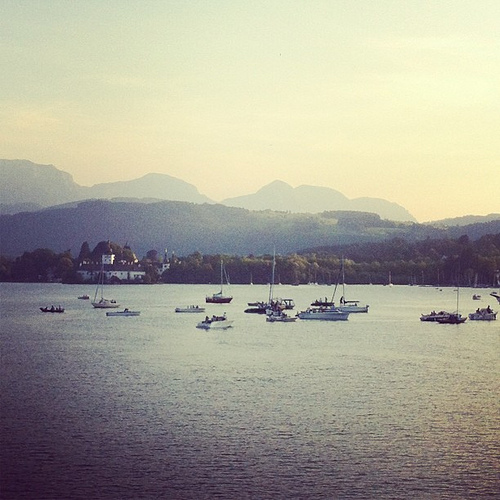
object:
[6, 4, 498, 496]
scene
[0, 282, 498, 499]
ocean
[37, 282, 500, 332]
boats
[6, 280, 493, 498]
water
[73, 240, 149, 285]
building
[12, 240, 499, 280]
background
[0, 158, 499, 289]
background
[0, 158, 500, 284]
hills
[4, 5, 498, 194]
sky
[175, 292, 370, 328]
boats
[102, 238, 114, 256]
steeple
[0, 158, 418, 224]
mountain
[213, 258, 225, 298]
pole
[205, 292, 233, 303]
boat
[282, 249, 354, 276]
trees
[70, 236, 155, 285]
house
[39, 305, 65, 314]
canoe